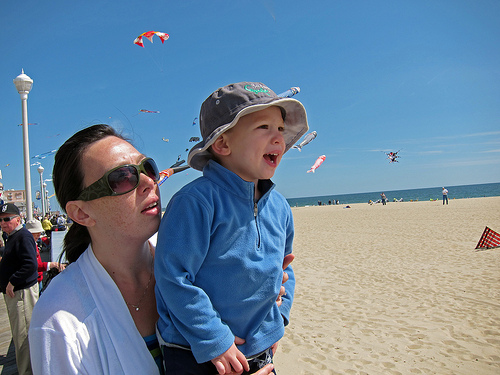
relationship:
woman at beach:
[71, 111, 155, 353] [351, 278, 373, 296]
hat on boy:
[220, 89, 244, 110] [207, 68, 309, 341]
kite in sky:
[130, 25, 174, 65] [269, 15, 326, 45]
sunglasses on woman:
[91, 154, 154, 198] [71, 111, 155, 353]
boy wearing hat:
[207, 68, 309, 341] [220, 89, 244, 110]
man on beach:
[440, 185, 459, 204] [351, 278, 373, 296]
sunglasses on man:
[91, 154, 154, 198] [440, 185, 459, 204]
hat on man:
[220, 89, 244, 110] [440, 185, 459, 204]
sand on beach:
[321, 301, 347, 354] [351, 278, 373, 296]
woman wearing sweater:
[71, 111, 155, 353] [195, 209, 232, 229]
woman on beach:
[71, 111, 155, 353] [351, 278, 373, 296]